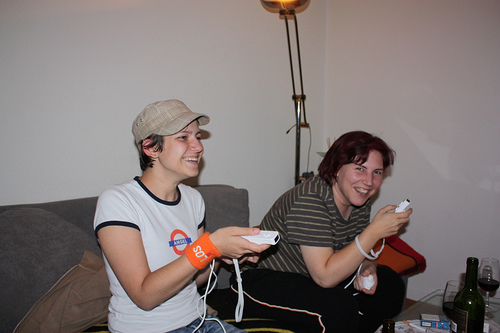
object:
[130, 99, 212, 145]
cap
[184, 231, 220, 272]
wristband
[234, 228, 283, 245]
game control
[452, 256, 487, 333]
bottle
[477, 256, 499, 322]
wine glass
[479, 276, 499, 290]
wine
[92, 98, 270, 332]
woman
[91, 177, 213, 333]
shirt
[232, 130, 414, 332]
woman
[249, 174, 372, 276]
shirt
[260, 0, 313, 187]
lamp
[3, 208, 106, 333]
cushion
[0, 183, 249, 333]
sofa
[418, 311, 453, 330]
cigarette pack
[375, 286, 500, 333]
coffee table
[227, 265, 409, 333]
pants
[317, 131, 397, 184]
hair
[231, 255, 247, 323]
wrist strap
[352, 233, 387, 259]
wrist strap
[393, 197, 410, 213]
game controller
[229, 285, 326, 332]
line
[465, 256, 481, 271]
top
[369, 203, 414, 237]
hand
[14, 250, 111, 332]
jacket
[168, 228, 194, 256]
logo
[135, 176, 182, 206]
trim